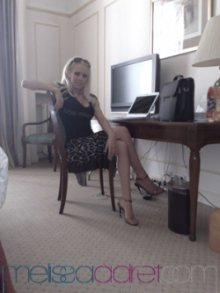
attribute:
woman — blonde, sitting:
[22, 56, 165, 226]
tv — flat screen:
[110, 54, 160, 112]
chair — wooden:
[46, 91, 116, 215]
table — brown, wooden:
[109, 114, 219, 241]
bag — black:
[159, 75, 194, 123]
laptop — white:
[115, 93, 159, 120]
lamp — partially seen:
[191, 16, 219, 120]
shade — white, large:
[192, 14, 219, 68]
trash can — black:
[167, 177, 191, 235]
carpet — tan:
[0, 162, 219, 293]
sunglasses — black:
[69, 57, 91, 67]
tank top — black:
[53, 83, 95, 139]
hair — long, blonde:
[61, 58, 94, 105]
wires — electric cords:
[134, 137, 218, 209]